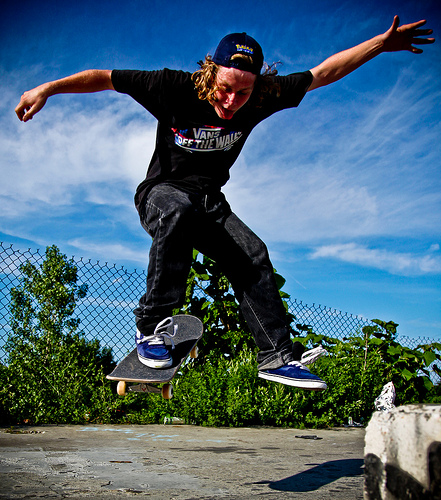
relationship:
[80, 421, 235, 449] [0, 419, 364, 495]
writing on ground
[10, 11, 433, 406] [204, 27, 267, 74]
man wearing baseball cap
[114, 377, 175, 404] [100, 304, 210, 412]
front wheels on skateboard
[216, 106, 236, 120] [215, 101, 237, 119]
tongue out of mouth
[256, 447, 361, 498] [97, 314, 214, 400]
shadow of skateboard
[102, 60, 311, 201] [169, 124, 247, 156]
shirt has writing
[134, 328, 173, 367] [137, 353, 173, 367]
shoe with sole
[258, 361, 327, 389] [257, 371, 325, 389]
shoe with sole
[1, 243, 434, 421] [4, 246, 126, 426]
fence behind bushes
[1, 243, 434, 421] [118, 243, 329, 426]
fence behind bushes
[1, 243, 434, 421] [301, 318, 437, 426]
fence behind bushes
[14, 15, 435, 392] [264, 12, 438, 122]
man has arm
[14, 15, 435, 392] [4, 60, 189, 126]
man has arm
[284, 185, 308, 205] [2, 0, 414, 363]
grey cloud in sky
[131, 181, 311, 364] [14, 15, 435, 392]
jeans of man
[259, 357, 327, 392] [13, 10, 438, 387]
shoe of skateboard